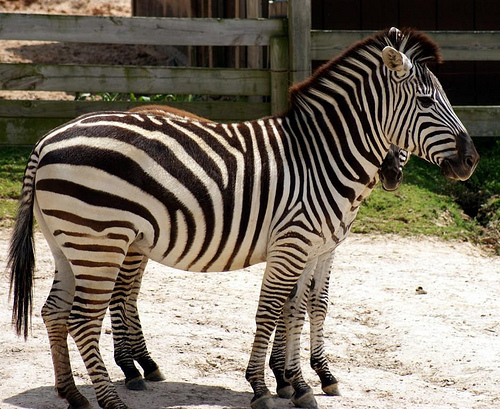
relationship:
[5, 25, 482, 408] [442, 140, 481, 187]
zebra has a nose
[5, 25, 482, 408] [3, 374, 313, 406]
zebra has a shadow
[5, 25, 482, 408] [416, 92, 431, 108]
zebra has an eye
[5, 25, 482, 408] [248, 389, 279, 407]
zebra has a hoof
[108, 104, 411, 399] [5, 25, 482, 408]
friend behind zebra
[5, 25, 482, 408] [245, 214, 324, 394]
zebra has a leg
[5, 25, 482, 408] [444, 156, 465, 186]
zebra has a mouth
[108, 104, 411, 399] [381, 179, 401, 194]
friend has teeth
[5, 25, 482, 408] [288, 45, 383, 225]
zebra has a neck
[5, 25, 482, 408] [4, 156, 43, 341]
zebra has a tail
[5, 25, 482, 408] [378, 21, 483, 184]
zebra has a head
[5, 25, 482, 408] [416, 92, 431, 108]
zebra has a eye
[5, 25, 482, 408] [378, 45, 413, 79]
zebra has a ear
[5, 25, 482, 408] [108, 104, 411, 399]
zebra with friend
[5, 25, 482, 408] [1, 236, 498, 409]
zebra on ground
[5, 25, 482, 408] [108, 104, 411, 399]
zebra and friend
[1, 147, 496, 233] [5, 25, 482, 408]
grass behind zebra